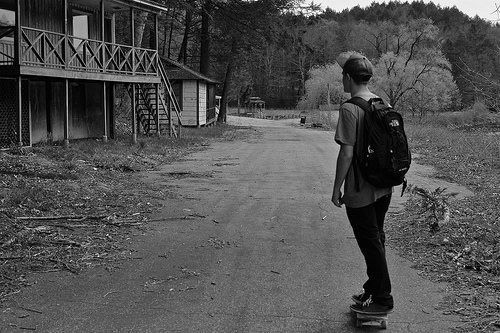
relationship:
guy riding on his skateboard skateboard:
[330, 52, 394, 313] [356, 302, 387, 328]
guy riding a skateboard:
[330, 52, 394, 313] [346, 285, 392, 327]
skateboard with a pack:
[346, 285, 392, 327] [342, 95, 411, 197]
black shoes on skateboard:
[346, 288, 396, 318] [356, 302, 387, 328]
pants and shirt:
[346, 194, 396, 308] [334, 94, 393, 209]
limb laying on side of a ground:
[11, 202, 118, 233] [13, 107, 498, 331]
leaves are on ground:
[448, 158, 498, 198] [13, 107, 498, 331]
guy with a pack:
[330, 52, 394, 313] [342, 95, 411, 197]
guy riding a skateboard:
[330, 52, 394, 313] [356, 302, 387, 328]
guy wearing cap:
[330, 52, 394, 313] [340, 48, 374, 79]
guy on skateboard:
[330, 52, 394, 313] [356, 302, 387, 328]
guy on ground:
[330, 52, 394, 313] [13, 107, 498, 331]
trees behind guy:
[118, 2, 498, 120] [330, 52, 394, 313]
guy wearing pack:
[320, 50, 410, 318] [342, 95, 411, 197]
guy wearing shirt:
[330, 52, 394, 313] [334, 94, 393, 209]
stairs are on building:
[121, 76, 182, 140] [0, 0, 184, 151]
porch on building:
[0, 22, 158, 83] [0, 0, 184, 151]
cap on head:
[340, 48, 374, 79] [335, 51, 375, 93]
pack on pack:
[342, 95, 411, 197] [342, 95, 411, 197]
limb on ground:
[11, 202, 118, 233] [13, 107, 498, 331]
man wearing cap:
[329, 48, 408, 315] [340, 48, 374, 79]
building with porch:
[3, 3, 184, 143] [0, 22, 163, 86]